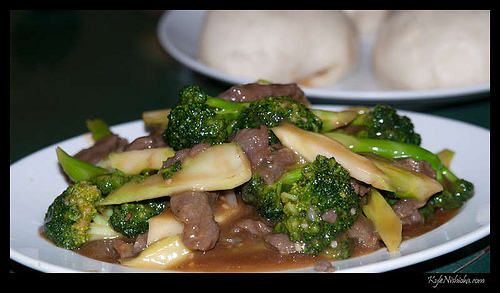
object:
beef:
[170, 191, 221, 252]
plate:
[9, 99, 499, 273]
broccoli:
[245, 151, 373, 258]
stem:
[203, 95, 245, 116]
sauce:
[199, 235, 297, 272]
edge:
[13, 140, 53, 162]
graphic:
[427, 273, 489, 292]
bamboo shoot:
[268, 121, 397, 194]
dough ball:
[194, 3, 361, 79]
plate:
[153, 6, 495, 101]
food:
[35, 78, 475, 268]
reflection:
[8, 245, 63, 276]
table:
[0, 0, 500, 145]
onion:
[222, 190, 242, 211]